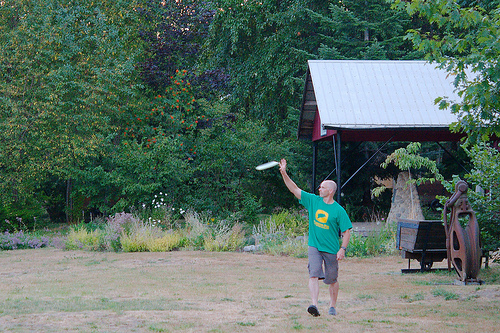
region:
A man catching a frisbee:
[253, 156, 351, 315]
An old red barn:
[298, 59, 498, 219]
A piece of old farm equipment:
[393, 178, 486, 285]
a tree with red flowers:
[123, 67, 205, 164]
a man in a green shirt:
[278, 156, 353, 318]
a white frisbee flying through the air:
[253, 156, 275, 171]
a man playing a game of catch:
[278, 155, 353, 317]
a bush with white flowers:
[143, 190, 185, 230]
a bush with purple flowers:
[1, 209, 49, 249]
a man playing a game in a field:
[278, 157, 352, 317]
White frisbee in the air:
[252, 161, 278, 172]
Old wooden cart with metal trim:
[395, 217, 445, 271]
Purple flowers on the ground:
[0, 230, 69, 253]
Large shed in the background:
[295, 59, 498, 236]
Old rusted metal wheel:
[443, 172, 488, 283]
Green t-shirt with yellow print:
[299, 189, 352, 254]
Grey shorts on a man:
[306, 247, 343, 287]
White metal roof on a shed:
[307, 56, 499, 127]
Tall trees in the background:
[0, 1, 420, 227]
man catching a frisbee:
[244, 144, 364, 306]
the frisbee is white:
[249, 155, 303, 204]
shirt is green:
[283, 178, 367, 270]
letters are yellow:
[308, 209, 345, 247]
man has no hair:
[312, 174, 351, 218]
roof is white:
[313, 47, 492, 139]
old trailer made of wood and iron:
[382, 181, 484, 296]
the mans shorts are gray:
[301, 245, 346, 285]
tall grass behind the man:
[79, 200, 231, 249]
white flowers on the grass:
[136, 188, 176, 223]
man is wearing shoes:
[296, 294, 346, 327]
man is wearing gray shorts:
[305, 226, 348, 292]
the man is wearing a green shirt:
[286, 175, 362, 271]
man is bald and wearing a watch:
[311, 175, 358, 266]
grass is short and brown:
[60, 265, 217, 330]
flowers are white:
[135, 185, 200, 241]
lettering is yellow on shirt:
[308, 206, 330, 237]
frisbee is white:
[249, 153, 294, 183]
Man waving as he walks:
[279, 154, 352, 316]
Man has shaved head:
[317, 174, 339, 201]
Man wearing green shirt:
[295, 189, 352, 253]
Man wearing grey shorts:
[303, 245, 340, 282]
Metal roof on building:
[298, 55, 498, 134]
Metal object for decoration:
[395, 179, 489, 281]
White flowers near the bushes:
[137, 187, 187, 228]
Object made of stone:
[385, 172, 427, 230]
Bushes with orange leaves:
[147, 61, 198, 156]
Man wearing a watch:
[335, 244, 351, 254]